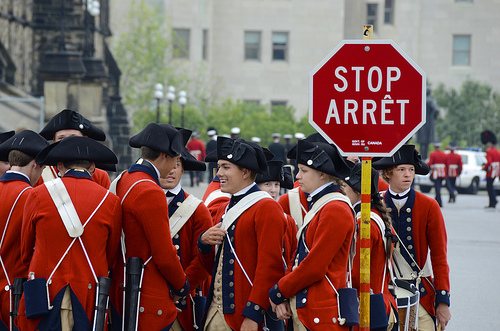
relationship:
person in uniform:
[193, 128, 292, 330] [225, 184, 327, 296]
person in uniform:
[270, 143, 356, 328] [297, 200, 351, 325]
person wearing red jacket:
[270, 143, 356, 328] [270, 187, 356, 329]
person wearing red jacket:
[378, 144, 450, 329] [198, 182, 285, 328]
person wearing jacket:
[19, 130, 109, 328] [102, 146, 182, 325]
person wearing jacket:
[108, 122, 186, 329] [113, 156, 194, 326]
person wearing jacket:
[193, 128, 292, 330] [14, 172, 119, 321]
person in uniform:
[270, 143, 356, 328] [194, 130, 285, 329]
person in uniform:
[193, 128, 292, 330] [194, 130, 285, 329]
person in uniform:
[378, 144, 450, 329] [194, 130, 285, 329]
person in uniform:
[108, 122, 186, 329] [194, 130, 285, 329]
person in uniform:
[19, 130, 109, 328] [194, 130, 285, 329]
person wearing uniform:
[378, 144, 450, 329] [378, 189, 450, 330]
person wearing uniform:
[270, 143, 356, 328] [378, 189, 450, 330]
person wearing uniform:
[193, 128, 292, 330] [378, 189, 450, 330]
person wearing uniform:
[108, 122, 186, 329] [378, 189, 450, 330]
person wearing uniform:
[19, 130, 109, 328] [378, 189, 450, 330]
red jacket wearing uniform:
[18, 171, 122, 329] [378, 189, 450, 330]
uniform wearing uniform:
[118, 169, 184, 329] [378, 189, 450, 330]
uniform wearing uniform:
[199, 187, 285, 328] [378, 189, 450, 330]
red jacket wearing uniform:
[270, 187, 356, 329] [378, 189, 450, 330]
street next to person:
[180, 181, 498, 329] [378, 144, 450, 329]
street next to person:
[180, 181, 498, 329] [425, 142, 447, 207]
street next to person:
[180, 181, 498, 329] [445, 144, 462, 203]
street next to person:
[180, 181, 498, 329] [108, 122, 186, 329]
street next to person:
[180, 181, 498, 329] [19, 130, 109, 328]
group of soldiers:
[0, 106, 456, 329] [1, 105, 450, 330]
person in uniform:
[19, 130, 109, 328] [19, 139, 126, 330]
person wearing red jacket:
[193, 128, 292, 330] [215, 196, 281, 328]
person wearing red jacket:
[378, 144, 450, 329] [270, 187, 356, 329]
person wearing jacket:
[19, 130, 109, 328] [17, 167, 125, 328]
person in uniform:
[19, 130, 109, 328] [13, 168, 125, 329]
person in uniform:
[108, 122, 186, 329] [111, 162, 194, 324]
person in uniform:
[193, 128, 292, 330] [199, 187, 285, 328]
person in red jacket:
[270, 143, 356, 328] [270, 187, 356, 329]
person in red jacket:
[378, 144, 450, 329] [384, 190, 451, 315]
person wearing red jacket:
[108, 122, 186, 329] [105, 167, 185, 329]